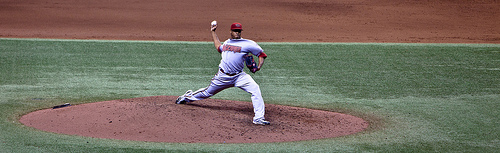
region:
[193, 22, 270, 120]
this is a baseball player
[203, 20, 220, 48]
the players right hand is behind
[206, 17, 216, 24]
the right hand is holding a ball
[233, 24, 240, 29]
the player is wearing a cap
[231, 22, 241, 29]
the cap is red in color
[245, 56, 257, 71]
he is wearing baseball glove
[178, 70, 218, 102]
the right leg is behind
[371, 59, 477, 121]
the pitch is green in color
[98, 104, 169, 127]
the soil is brown in color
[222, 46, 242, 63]
the jersey is white in color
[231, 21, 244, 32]
this is a baseball cap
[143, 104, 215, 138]
the ground is sandy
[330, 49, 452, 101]
this is the grass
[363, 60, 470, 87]
the grass is green in color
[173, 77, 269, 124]
the feet are apart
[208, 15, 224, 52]
the man is holding the tennis ball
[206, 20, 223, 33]
the tennis ball is white in color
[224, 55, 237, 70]
the t-shirt is white in color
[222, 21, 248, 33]
the man has a red cape on his head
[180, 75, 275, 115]
the pants are white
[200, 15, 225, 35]
the tennis ball is white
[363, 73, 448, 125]
the grass is green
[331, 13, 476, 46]
the court is brown red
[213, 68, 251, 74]
the belt is black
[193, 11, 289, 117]
the man is about to throw the ball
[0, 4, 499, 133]
the man is in a baseball pitch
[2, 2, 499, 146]
the photo was taken during the day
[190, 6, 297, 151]
the man has his legs stretched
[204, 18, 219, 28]
this is a baseball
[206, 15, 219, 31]
the baseball is white in color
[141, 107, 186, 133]
the ground is sandy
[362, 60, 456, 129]
this is the grass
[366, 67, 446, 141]
the grass is green in color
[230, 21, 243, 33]
this is a cap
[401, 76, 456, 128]
part of some grass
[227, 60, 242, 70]
part of a white top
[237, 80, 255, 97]
part of a white pant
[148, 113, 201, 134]
part of a brown ground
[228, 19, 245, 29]
part of a red cap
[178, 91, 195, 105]
part of a sport shoe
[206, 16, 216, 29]
a round white baseball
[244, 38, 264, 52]
part of a shoulder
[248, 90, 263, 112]
left leg of a player